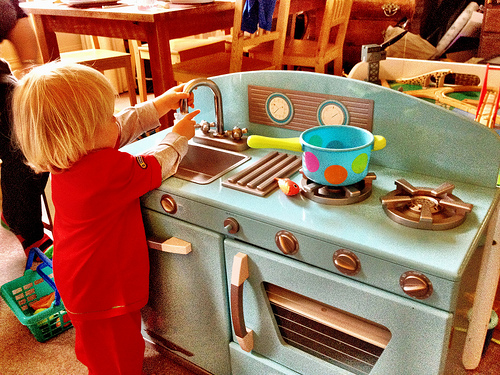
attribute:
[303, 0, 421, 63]
bureau — light, brown, wood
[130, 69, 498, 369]
kitchen — child's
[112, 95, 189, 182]
shirt — beige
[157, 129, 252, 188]
sink — child sized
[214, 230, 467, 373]
oven door — child sized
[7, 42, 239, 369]
toddler — blond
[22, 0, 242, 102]
table — brown, wood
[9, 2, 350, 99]
chairs — wood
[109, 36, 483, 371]
stove — chrome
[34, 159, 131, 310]
casual shirt — child's, red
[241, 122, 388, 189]
toy pot — blue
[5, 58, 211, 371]
toddler — blonde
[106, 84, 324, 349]
beige door — brown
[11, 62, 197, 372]
child — blonde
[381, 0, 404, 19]
handles — gold